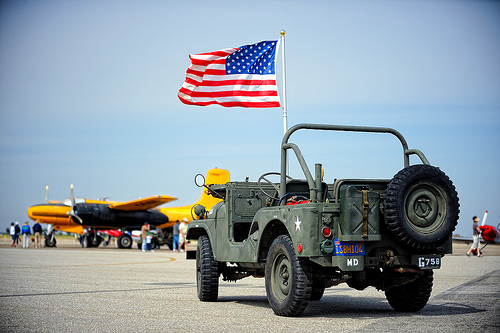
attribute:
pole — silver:
[277, 29, 292, 184]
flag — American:
[175, 37, 282, 105]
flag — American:
[163, 22, 289, 115]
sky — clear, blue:
[11, 7, 496, 139]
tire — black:
[382, 163, 461, 258]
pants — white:
[470, 234, 480, 249]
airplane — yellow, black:
[19, 177, 248, 266]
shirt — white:
[178, 222, 190, 235]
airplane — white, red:
[479, 217, 499, 252]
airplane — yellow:
[16, 177, 171, 260]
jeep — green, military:
[189, 120, 455, 312]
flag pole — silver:
[269, 30, 291, 150]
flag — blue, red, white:
[167, 35, 287, 124]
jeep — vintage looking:
[180, 118, 465, 323]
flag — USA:
[178, 26, 288, 125]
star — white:
[289, 216, 306, 233]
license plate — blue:
[332, 234, 369, 251]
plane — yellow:
[22, 162, 234, 252]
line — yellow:
[40, 241, 187, 274]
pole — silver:
[279, 30, 288, 150]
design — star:
[287, 206, 310, 241]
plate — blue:
[336, 238, 376, 258]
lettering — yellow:
[338, 241, 366, 253]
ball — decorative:
[280, 25, 288, 40]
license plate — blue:
[334, 242, 364, 258]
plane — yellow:
[19, 170, 244, 250]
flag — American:
[181, 30, 289, 168]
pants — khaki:
[175, 233, 186, 246]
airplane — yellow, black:
[19, 168, 229, 255]